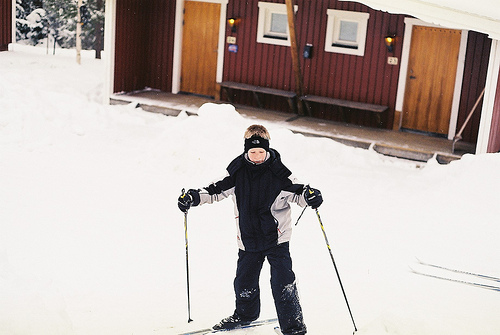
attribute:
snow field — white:
[353, 168, 449, 223]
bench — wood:
[293, 87, 390, 126]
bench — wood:
[221, 77, 296, 114]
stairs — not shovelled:
[368, 141, 440, 173]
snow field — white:
[9, 82, 491, 334]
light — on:
[379, 28, 398, 53]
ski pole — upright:
[178, 187, 193, 326]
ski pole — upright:
[303, 182, 360, 334]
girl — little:
[210, 119, 324, 331]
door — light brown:
[384, 22, 466, 140]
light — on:
[224, 12, 243, 34]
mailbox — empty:
[302, 42, 312, 59]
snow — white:
[2, 55, 498, 335]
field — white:
[0, 33, 496, 333]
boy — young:
[142, 97, 392, 332]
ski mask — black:
[244, 154, 269, 172]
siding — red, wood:
[224, 3, 404, 108]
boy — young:
[178, 121, 327, 333]